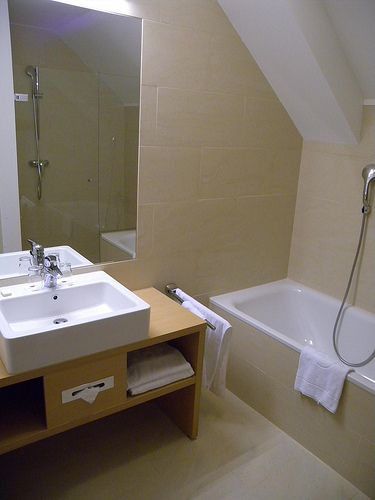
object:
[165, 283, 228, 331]
rack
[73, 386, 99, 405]
tissue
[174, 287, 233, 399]
towel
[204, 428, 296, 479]
floor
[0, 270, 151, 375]
sink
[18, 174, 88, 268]
glass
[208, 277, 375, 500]
tub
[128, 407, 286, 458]
mat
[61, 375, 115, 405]
dispenser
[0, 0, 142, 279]
mirror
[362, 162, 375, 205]
shower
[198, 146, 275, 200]
tile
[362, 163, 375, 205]
head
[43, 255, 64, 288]
faucet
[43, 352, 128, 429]
box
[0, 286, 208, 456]
cabinet